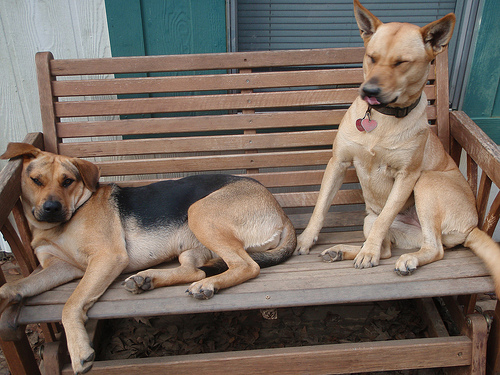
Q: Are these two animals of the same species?
A: Yes, all the animals are dogs.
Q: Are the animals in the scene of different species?
A: No, all the animals are dogs.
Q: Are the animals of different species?
A: No, all the animals are dogs.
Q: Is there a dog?
A: Yes, there is a dog.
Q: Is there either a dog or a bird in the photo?
A: Yes, there is a dog.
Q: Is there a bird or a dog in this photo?
A: Yes, there is a dog.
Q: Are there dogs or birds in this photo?
A: Yes, there is a dog.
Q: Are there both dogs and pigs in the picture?
A: No, there is a dog but no pigs.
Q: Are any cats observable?
A: No, there are no cats.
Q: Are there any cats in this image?
A: No, there are no cats.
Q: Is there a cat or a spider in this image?
A: No, there are no cats or spiders.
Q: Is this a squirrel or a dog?
A: This is a dog.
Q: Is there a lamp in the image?
A: No, there are no lamps.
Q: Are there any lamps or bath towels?
A: No, there are no lamps or bath towels.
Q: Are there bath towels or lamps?
A: No, there are no lamps or bath towels.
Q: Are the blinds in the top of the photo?
A: Yes, the blinds are in the top of the image.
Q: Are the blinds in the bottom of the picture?
A: No, the blinds are in the top of the image.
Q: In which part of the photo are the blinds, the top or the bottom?
A: The blinds are in the top of the image.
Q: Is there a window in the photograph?
A: Yes, there is a window.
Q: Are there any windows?
A: Yes, there is a window.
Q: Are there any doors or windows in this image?
A: Yes, there is a window.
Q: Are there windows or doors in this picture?
A: Yes, there is a window.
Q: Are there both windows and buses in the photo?
A: No, there is a window but no buses.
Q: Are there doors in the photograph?
A: No, there are no doors.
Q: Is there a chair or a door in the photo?
A: No, there are no doors or chairs.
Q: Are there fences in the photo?
A: No, there are no fences.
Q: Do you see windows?
A: Yes, there is a window.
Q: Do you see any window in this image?
A: Yes, there is a window.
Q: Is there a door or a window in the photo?
A: Yes, there is a window.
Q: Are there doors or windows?
A: Yes, there is a window.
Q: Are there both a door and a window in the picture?
A: No, there is a window but no doors.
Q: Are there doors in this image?
A: No, there are no doors.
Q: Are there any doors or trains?
A: No, there are no doors or trains.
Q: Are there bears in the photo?
A: No, there are no bears.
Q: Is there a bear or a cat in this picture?
A: No, there are no bears or cats.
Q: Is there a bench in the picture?
A: Yes, there is a bench.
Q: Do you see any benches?
A: Yes, there is a bench.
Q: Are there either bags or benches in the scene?
A: Yes, there is a bench.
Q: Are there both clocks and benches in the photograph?
A: No, there is a bench but no clocks.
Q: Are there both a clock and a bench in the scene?
A: No, there is a bench but no clocks.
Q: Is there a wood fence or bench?
A: Yes, there is a wood bench.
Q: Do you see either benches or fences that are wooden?
A: Yes, the bench is wooden.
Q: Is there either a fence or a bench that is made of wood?
A: Yes, the bench is made of wood.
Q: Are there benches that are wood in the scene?
A: Yes, there is a wood bench.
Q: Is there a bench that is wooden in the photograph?
A: Yes, there is a wood bench.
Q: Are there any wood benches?
A: Yes, there is a wood bench.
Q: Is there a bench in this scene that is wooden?
A: Yes, there is a bench that is wooden.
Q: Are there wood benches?
A: Yes, there is a bench that is made of wood.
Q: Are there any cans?
A: No, there are no cans.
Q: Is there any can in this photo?
A: No, there are no cans.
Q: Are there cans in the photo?
A: No, there are no cans.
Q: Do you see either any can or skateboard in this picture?
A: No, there are no cans or skateboards.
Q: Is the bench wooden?
A: Yes, the bench is wooden.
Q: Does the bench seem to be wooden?
A: Yes, the bench is wooden.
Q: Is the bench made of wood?
A: Yes, the bench is made of wood.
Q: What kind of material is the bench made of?
A: The bench is made of wood.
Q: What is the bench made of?
A: The bench is made of wood.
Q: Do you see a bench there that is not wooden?
A: No, there is a bench but it is wooden.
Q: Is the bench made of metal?
A: No, the bench is made of wood.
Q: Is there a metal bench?
A: No, there is a bench but it is made of wood.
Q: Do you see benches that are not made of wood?
A: No, there is a bench but it is made of wood.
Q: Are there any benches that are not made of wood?
A: No, there is a bench but it is made of wood.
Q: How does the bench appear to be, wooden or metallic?
A: The bench is wooden.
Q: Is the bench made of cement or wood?
A: The bench is made of wood.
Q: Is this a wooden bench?
A: Yes, this is a wooden bench.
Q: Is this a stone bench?
A: No, this is a wooden bench.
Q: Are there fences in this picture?
A: No, there are no fences.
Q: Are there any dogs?
A: Yes, there is a dog.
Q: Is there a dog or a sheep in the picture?
A: Yes, there is a dog.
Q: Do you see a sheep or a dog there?
A: Yes, there is a dog.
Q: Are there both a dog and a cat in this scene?
A: No, there is a dog but no cats.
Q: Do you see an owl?
A: No, there are no owls.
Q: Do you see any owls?
A: No, there are no owls.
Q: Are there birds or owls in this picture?
A: No, there are no owls or birds.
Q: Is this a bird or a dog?
A: This is a dog.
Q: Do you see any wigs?
A: No, there are no wigs.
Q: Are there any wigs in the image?
A: No, there are no wigs.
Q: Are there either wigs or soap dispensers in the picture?
A: No, there are no wigs or soap dispensers.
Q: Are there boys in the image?
A: No, there are no boys.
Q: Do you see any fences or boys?
A: No, there are no boys or fences.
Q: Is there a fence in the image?
A: No, there are no fences.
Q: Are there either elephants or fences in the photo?
A: No, there are no fences or elephants.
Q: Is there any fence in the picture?
A: No, there are no fences.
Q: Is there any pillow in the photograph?
A: No, there are no pillows.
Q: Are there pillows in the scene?
A: No, there are no pillows.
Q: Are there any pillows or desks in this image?
A: No, there are no pillows or desks.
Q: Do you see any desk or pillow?
A: No, there are no pillows or desks.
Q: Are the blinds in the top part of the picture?
A: Yes, the blinds are in the top of the image.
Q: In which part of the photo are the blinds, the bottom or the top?
A: The blinds are in the top of the image.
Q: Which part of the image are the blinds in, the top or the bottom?
A: The blinds are in the top of the image.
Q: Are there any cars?
A: No, there are no cars.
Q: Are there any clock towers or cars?
A: No, there are no cars or clock towers.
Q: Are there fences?
A: No, there are no fences.